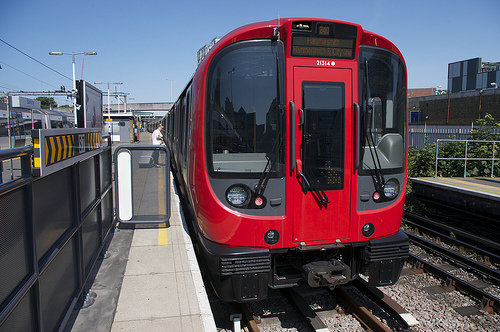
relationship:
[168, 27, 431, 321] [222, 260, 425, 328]
train sitting on tracks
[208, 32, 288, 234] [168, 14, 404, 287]
windshield of train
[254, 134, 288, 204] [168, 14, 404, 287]
windshield wiper on train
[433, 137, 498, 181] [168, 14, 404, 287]
fence to right of train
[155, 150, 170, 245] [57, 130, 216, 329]
paint on walkway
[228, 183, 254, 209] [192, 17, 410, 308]
light on front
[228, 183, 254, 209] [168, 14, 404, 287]
light on train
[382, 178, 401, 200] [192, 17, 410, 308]
light on front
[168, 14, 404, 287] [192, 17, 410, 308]
train has front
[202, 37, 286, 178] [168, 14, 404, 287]
window of train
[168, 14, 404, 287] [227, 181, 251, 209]
train has headlight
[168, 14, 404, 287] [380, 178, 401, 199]
train has headlight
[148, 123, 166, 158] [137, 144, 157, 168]
person with bag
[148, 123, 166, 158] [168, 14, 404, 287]
person boards train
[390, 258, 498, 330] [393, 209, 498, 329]
base for tracks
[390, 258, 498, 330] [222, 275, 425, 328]
base for tracks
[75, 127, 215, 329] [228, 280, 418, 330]
sidewalk borders train tracks